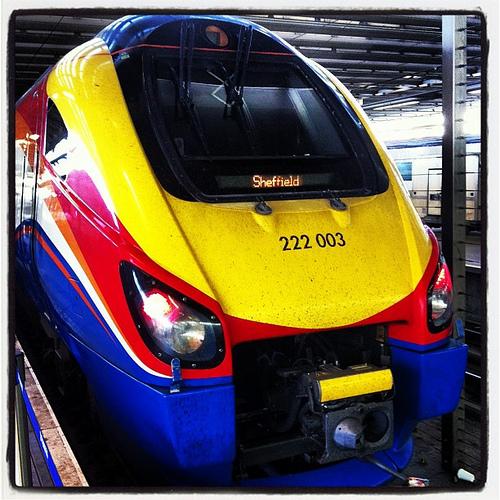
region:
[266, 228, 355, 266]
number on the train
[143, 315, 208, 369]
light on the train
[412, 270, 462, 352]
light on the train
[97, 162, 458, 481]
train on the track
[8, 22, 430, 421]
train on the track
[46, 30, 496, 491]
front part of a train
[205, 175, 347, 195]
digital sign on front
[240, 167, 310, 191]
orange writing on sign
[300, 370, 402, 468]
yellow safety ram on front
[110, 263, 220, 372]
light on front of train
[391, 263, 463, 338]
light on front of train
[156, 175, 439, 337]
yellow front of train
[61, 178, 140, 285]
red on front of train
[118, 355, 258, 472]
blue on bottom of train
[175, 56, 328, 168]
black front window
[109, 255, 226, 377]
a right front headlight.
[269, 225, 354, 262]
A number on a train.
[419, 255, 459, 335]
a headlight on a train.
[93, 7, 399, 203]
a windshield on a train.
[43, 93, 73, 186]
a window on the side of a train.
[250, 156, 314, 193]
a sign in a train window.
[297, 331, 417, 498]
the front of a train.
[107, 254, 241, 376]
a light on a train.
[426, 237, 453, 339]
a front left headlight.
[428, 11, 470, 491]
a pole near a train.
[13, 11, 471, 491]
yellow, red and blue train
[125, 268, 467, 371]
headlights on front of train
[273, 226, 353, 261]
numbers in black print on front of train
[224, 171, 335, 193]
digital window on front of train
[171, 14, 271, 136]
winshield wipers on front of train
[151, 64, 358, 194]
windshield on front of train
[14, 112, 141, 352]
orange stripe on side of train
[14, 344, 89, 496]
platform next to train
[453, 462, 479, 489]
white paper cup on ground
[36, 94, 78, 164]
window on side of train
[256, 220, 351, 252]
numbers 222 003 on a train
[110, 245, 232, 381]
a black train head light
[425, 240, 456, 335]
a black train head light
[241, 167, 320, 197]
sheffield on a train display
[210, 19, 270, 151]
a wind shield wiper on a train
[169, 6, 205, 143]
a wind shield wiper on a train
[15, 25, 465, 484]
a multi colored electric train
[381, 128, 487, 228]
a train car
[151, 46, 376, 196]
a train wind shield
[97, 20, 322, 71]
a red line